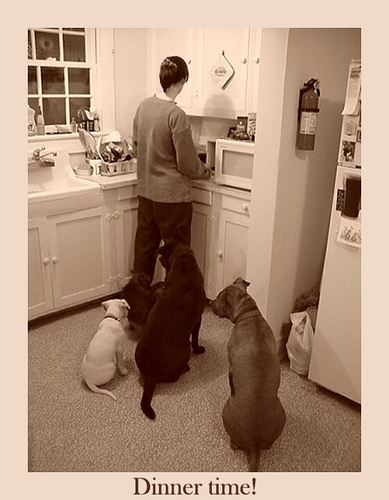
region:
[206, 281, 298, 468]
adult dog waiting on food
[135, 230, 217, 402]
large black dog waiting for food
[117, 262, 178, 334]
adult cat waiting for food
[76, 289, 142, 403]
small white dog with dark collar waiting for food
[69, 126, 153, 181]
clean dishes drying in drainer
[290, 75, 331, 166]
fire extinguisher hanging on side of wall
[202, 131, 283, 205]
white microwave sitting on cabinet top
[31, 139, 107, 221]
kitchen sink with faucet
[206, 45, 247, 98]
white pot holder hanging on cabinet front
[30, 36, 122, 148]
kitchen window with white panes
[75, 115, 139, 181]
pots and pans drying near the sink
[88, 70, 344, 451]
three dogs waiting to be feed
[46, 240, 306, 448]
three dogs and a cat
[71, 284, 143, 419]
a small white dog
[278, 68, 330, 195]
a fire extinguisher hanging on a white wall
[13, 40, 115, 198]
a window above a sink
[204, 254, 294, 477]
a large brown dog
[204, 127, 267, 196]
a white microwave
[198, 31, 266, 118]
two white hanging cabinets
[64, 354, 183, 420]
two dog tails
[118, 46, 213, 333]
a woman standing in kitchen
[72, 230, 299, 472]
three dogs and one cat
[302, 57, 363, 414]
a refrigerator with papers on the front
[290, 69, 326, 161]
a fire extinguisher hanging on the wall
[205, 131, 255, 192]
a microwave sitting on counter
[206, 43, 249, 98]
a hot pad hanging on cupboard door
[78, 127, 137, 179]
dishes sitting in rack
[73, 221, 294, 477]
the three dogs are sitting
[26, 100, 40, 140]
dish soap sitting on windowsill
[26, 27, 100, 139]
window is above the sink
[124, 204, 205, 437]
a medium sized black dog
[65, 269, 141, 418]
a tiny white dog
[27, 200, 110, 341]
two white cabinet doors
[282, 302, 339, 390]
a white plastic bag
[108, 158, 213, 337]
These are black jeans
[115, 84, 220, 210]
a gray sweat shirt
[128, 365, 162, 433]
a black dog tail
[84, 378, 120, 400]
a white dog tail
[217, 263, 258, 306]
two brown dog ears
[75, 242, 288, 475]
Three dogs and a cat.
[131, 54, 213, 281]
Woman standing at a kitchen counter.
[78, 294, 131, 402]
White dog wearing a collar sitting on the kitchen floor.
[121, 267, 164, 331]
Cat waiting to be fed.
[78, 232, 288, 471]
White dog, black dog and brown dog.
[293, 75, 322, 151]
Fire extinguisher.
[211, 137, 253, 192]
White microwave oven.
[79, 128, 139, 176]
Dryer rack loaded with items.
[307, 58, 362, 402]
White refrigerator.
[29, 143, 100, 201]
Kitchen sink and silver faucet.